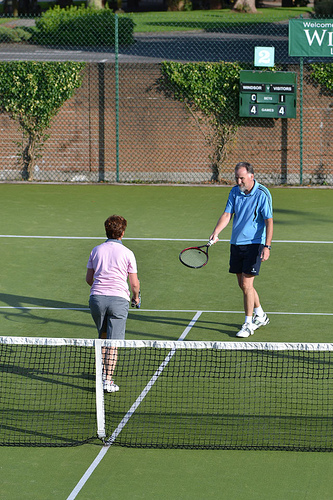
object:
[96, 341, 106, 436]
line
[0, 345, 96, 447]
net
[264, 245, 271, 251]
watch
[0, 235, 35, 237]
line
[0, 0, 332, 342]
court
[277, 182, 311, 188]
ground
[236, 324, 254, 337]
tennis shoe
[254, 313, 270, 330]
tennis shoe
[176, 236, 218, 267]
racket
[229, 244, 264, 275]
short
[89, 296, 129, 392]
person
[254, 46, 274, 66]
sign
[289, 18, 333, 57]
sign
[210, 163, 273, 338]
man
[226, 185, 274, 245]
blue shirt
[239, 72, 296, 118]
scoreboard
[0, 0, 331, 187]
fence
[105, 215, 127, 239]
brownhair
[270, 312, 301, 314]
line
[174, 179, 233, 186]
ground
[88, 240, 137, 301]
shirt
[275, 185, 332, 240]
floor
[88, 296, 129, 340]
shorts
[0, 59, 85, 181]
trees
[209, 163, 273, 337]
person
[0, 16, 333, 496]
tennis court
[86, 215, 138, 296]
person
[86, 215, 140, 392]
woman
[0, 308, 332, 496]
court